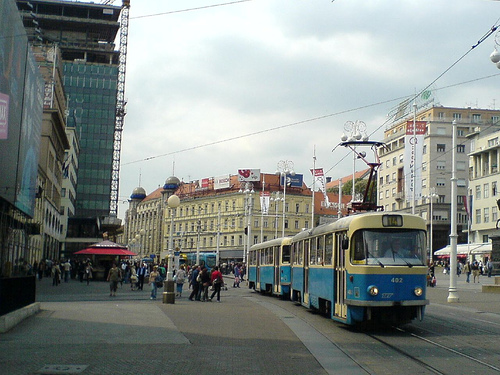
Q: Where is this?
A: This is at the street.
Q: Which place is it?
A: It is a street.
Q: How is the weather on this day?
A: It is cloudy.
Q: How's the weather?
A: It is cloudy.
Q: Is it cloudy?
A: Yes, it is cloudy.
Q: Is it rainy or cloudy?
A: It is cloudy.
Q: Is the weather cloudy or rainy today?
A: It is cloudy.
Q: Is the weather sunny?
A: No, it is cloudy.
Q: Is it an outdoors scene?
A: Yes, it is outdoors.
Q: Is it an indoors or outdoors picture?
A: It is outdoors.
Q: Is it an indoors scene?
A: No, it is outdoors.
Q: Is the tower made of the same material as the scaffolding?
A: Yes, both the tower and the scaffolding are made of metal.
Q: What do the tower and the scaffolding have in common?
A: The material, both the tower and the scaffolding are metallic.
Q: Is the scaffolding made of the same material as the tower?
A: Yes, both the scaffolding and the tower are made of metal.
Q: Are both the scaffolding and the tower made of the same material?
A: Yes, both the scaffolding and the tower are made of metal.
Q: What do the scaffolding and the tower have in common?
A: The material, both the scaffolding and the tower are metallic.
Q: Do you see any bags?
A: No, there are no bags.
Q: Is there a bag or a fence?
A: No, there are no bags or fences.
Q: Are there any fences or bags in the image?
A: No, there are no bags or fences.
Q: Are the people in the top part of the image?
A: No, the people are in the bottom of the image.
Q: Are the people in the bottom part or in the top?
A: The people are in the bottom of the image.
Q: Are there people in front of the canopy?
A: Yes, there are people in front of the canopy.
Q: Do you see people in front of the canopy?
A: Yes, there are people in front of the canopy.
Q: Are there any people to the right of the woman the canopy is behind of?
A: Yes, there are people to the right of the woman.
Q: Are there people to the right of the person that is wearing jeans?
A: Yes, there are people to the right of the woman.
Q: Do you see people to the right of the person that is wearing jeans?
A: Yes, there are people to the right of the woman.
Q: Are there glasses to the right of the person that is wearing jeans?
A: No, there are people to the right of the woman.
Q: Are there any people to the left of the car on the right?
A: Yes, there are people to the left of the car.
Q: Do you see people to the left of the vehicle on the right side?
A: Yes, there are people to the left of the car.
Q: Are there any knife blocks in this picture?
A: No, there are no knife blocks.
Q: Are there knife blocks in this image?
A: No, there are no knife blocks.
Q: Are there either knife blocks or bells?
A: No, there are no knife blocks or bells.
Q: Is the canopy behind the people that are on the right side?
A: Yes, the canopy is behind the people.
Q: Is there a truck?
A: No, there are no trucks.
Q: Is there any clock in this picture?
A: No, there are no clocks.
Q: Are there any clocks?
A: No, there are no clocks.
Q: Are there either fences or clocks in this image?
A: No, there are no clocks or fences.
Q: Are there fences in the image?
A: No, there are no fences.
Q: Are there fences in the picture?
A: No, there are no fences.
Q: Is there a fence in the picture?
A: No, there are no fences.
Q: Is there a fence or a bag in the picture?
A: No, there are no fences or bags.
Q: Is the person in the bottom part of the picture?
A: Yes, the person is in the bottom of the image.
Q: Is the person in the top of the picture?
A: No, the person is in the bottom of the image.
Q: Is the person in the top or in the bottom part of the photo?
A: The person is in the bottom of the image.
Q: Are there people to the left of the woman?
A: Yes, there is a person to the left of the woman.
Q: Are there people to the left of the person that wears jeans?
A: Yes, there is a person to the left of the woman.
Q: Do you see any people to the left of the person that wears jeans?
A: Yes, there is a person to the left of the woman.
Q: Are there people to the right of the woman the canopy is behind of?
A: No, the person is to the left of the woman.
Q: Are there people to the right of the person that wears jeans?
A: No, the person is to the left of the woman.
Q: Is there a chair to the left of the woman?
A: No, there is a person to the left of the woman.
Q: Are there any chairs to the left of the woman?
A: No, there is a person to the left of the woman.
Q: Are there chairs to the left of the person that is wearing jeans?
A: No, there is a person to the left of the woman.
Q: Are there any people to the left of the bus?
A: Yes, there is a person to the left of the bus.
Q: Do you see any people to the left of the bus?
A: Yes, there is a person to the left of the bus.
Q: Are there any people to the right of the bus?
A: No, the person is to the left of the bus.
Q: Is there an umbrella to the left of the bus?
A: No, there is a person to the left of the bus.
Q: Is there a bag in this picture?
A: No, there are no bags.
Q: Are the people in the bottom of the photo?
A: Yes, the people are in the bottom of the image.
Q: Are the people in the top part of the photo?
A: No, the people are in the bottom of the image.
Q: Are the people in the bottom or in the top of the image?
A: The people are in the bottom of the image.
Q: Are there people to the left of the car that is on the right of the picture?
A: Yes, there are people to the left of the car.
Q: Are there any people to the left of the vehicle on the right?
A: Yes, there are people to the left of the car.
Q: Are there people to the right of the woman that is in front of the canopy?
A: Yes, there are people to the right of the woman.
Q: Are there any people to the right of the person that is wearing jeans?
A: Yes, there are people to the right of the woman.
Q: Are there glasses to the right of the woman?
A: No, there are people to the right of the woman.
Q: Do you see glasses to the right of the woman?
A: No, there are people to the right of the woman.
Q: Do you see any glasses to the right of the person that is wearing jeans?
A: No, there are people to the right of the woman.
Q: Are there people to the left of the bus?
A: Yes, there are people to the left of the bus.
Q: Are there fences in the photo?
A: No, there are no fences.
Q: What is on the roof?
A: The sign is on the roof.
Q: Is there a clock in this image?
A: No, there are no clocks.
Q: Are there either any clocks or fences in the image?
A: No, there are no clocks or fences.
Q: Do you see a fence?
A: No, there are no fences.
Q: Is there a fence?
A: No, there are no fences.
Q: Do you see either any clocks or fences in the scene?
A: No, there are no fences or clocks.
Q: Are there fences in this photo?
A: No, there are no fences.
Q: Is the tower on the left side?
A: Yes, the tower is on the left of the image.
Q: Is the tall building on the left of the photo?
A: Yes, the tower is on the left of the image.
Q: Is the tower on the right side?
A: No, the tower is on the left of the image.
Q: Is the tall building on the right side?
A: No, the tower is on the left of the image.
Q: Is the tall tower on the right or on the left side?
A: The tower is on the left of the image.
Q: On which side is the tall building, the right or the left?
A: The tower is on the left of the image.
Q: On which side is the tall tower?
A: The tower is on the left of the image.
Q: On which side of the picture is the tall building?
A: The tower is on the left of the image.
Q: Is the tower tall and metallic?
A: Yes, the tower is tall and metallic.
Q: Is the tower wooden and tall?
A: No, the tower is tall but metallic.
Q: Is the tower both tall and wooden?
A: No, the tower is tall but metallic.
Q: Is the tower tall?
A: Yes, the tower is tall.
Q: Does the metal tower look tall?
A: Yes, the tower is tall.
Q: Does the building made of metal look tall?
A: Yes, the tower is tall.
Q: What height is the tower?
A: The tower is tall.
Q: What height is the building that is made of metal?
A: The tower is tall.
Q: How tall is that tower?
A: The tower is tall.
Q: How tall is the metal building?
A: The tower is tall.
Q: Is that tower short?
A: No, the tower is tall.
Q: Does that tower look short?
A: No, the tower is tall.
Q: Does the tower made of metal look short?
A: No, the tower is tall.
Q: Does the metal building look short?
A: No, the tower is tall.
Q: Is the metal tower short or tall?
A: The tower is tall.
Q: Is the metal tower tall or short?
A: The tower is tall.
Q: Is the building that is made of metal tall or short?
A: The tower is tall.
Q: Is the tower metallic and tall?
A: Yes, the tower is metallic and tall.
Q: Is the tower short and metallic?
A: No, the tower is metallic but tall.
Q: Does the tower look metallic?
A: Yes, the tower is metallic.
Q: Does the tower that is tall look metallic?
A: Yes, the tower is metallic.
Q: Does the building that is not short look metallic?
A: Yes, the tower is metallic.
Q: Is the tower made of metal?
A: Yes, the tower is made of metal.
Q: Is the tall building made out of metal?
A: Yes, the tower is made of metal.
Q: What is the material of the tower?
A: The tower is made of metal.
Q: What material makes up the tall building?
A: The tower is made of metal.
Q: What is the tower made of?
A: The tower is made of metal.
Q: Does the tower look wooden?
A: No, the tower is metallic.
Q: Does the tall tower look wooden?
A: No, the tower is metallic.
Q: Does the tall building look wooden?
A: No, the tower is metallic.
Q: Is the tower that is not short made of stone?
A: No, the tower is made of metal.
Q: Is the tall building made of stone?
A: No, the tower is made of metal.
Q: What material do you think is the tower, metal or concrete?
A: The tower is made of metal.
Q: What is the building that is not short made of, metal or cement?
A: The tower is made of metal.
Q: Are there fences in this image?
A: No, there are no fences.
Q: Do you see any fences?
A: No, there are no fences.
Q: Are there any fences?
A: No, there are no fences.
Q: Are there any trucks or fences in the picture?
A: No, there are no fences or trucks.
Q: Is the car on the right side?
A: Yes, the car is on the right of the image.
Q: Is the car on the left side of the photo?
A: No, the car is on the right of the image.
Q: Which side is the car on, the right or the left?
A: The car is on the right of the image.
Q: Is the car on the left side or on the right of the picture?
A: The car is on the right of the image.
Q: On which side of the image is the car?
A: The car is on the right of the image.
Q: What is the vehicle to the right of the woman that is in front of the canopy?
A: The vehicle is a car.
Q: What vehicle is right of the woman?
A: The vehicle is a car.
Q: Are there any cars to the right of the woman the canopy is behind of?
A: Yes, there is a car to the right of the woman.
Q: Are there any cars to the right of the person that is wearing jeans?
A: Yes, there is a car to the right of the woman.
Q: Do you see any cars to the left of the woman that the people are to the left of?
A: No, the car is to the right of the woman.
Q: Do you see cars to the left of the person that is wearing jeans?
A: No, the car is to the right of the woman.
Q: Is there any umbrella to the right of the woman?
A: No, there is a car to the right of the woman.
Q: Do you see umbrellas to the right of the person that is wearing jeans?
A: No, there is a car to the right of the woman.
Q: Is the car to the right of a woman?
A: Yes, the car is to the right of a woman.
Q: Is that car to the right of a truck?
A: No, the car is to the right of a woman.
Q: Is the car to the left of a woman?
A: No, the car is to the right of a woman.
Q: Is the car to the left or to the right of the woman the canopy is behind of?
A: The car is to the right of the woman.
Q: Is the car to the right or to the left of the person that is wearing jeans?
A: The car is to the right of the woman.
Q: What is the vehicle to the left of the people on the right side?
A: The vehicle is a car.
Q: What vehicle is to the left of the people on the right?
A: The vehicle is a car.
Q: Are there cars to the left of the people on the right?
A: Yes, there is a car to the left of the people.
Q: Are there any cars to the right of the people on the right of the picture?
A: No, the car is to the left of the people.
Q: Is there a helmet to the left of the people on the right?
A: No, there is a car to the left of the people.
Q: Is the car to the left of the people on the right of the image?
A: Yes, the car is to the left of the people.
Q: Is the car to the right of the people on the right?
A: No, the car is to the left of the people.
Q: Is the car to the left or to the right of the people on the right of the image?
A: The car is to the left of the people.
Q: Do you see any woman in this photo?
A: Yes, there is a woman.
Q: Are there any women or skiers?
A: Yes, there is a woman.